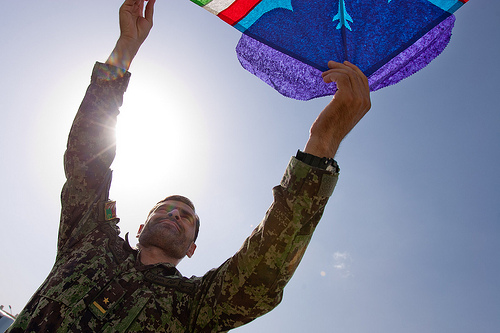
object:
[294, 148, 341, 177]
watch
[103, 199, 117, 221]
badge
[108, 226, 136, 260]
shoulder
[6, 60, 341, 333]
uniform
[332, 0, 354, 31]
plane image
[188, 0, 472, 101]
fabric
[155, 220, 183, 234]
mouth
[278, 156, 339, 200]
cuff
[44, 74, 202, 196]
sun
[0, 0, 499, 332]
sky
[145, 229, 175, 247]
chin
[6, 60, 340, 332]
army uniform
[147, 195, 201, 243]
hair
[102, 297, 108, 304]
star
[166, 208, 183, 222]
nose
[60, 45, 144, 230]
arm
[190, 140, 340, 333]
arm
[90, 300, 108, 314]
yellow stripe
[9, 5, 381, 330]
soldier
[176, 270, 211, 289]
shoulder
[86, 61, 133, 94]
cuff